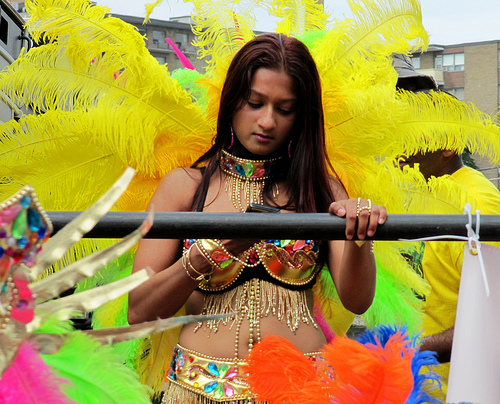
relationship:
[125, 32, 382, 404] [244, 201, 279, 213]
woman looking at phone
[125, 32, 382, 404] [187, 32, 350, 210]
woman has hair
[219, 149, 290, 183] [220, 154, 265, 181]
gems has gems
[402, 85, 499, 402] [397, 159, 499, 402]
person wearing shirt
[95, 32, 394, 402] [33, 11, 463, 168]
woman wearing feathers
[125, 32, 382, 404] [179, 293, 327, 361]
woman has stomach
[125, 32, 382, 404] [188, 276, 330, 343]
woman wearing beads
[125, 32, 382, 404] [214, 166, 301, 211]
woman wearing beads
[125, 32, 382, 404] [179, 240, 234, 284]
woman wearing bracelets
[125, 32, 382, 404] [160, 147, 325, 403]
woman wearing costume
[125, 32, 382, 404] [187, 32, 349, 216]
woman has hair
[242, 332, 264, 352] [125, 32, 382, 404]
belly button part of woman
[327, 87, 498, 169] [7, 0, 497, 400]
feather part of outfit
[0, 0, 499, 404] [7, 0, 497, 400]
feather part of outfit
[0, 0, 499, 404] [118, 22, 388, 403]
feather part of outfit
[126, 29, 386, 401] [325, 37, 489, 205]
dancer dressed in feathers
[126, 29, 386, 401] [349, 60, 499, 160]
dancer dressed in feathers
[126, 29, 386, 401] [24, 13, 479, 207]
dancer dressed in feathers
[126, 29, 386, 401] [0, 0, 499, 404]
dancer dressed in feather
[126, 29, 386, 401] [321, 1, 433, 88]
dancer dressed in feathers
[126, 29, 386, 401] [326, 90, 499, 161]
dancer dressed in feathers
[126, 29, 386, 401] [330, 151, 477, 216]
dancer dressed in feathers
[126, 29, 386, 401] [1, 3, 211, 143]
dancer dressed in feathers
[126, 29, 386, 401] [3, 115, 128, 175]
dancer dressed in feathers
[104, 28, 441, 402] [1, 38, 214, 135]
dancer dressed in feather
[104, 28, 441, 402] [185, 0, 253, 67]
dancer dressed in feather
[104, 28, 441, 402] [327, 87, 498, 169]
dancer dressed in feather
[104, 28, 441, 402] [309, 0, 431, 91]
dancer dressed in feather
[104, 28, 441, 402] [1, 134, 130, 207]
dancer dressed in feather